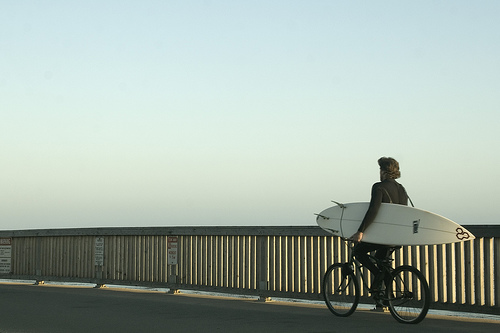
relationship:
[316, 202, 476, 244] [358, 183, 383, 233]
surfboard under arm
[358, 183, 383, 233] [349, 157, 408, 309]
arm of man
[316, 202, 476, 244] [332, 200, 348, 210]
surfboard has fin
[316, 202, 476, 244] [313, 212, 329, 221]
surfboard has fin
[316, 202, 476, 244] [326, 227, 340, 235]
surfboard has fin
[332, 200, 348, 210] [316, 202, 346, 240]
fin in tail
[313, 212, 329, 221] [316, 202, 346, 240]
fin in tail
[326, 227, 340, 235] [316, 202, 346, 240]
fin in tail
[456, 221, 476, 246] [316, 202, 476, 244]
nose of surfboard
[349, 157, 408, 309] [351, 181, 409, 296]
man wears wetsuit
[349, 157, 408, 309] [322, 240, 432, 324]
man sits in bike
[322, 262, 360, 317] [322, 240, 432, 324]
wheel of bike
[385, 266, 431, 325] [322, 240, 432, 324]
wheel of bike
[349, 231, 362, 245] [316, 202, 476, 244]
hand holding surfboard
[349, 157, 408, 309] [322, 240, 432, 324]
man on bike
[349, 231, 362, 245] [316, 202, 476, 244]
hand holding on to surfboard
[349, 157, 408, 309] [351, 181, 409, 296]
man in wetsuit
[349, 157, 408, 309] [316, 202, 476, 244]
man holding surfboard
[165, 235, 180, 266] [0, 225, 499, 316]
sign on fence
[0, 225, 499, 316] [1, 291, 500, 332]
fence on edge of street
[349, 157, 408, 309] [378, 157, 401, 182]
man with hair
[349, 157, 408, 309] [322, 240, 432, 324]
man riding bike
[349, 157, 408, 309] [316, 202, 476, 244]
man carrying surfboard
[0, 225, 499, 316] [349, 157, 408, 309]
fence near man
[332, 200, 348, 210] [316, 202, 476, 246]
fin on bottom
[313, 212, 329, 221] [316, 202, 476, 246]
fin on bottom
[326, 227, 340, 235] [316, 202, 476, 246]
fin on bottom